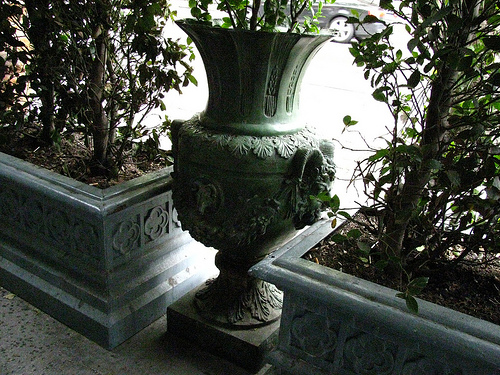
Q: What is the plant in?
A: Pot.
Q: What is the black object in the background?
A: Car.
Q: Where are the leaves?
A: On the bush.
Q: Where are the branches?
A: On the shrub.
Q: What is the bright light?
A: Sunshine.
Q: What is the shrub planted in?
A: Carved rectangle container.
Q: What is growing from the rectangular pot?
A: Shrubs.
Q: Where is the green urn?
A: Between two rectangular pots.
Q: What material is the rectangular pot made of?
A: Marble.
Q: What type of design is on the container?
A: Clover.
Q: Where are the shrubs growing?
A: In a rectangular pot.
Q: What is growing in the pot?
A: Bushes.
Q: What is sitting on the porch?
A: Stone planter.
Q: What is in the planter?
A: Flowers.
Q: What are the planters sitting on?
A: A front porch.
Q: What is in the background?
A: A black car.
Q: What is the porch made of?
A: Cement.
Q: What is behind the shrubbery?
A: A car.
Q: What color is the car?
A: Black.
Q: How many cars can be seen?
A: One.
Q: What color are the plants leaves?
A: Green.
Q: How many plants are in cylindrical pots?
A: One.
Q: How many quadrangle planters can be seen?
A: Two.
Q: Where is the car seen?
A: Behind the plants.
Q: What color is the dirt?
A: Brown.